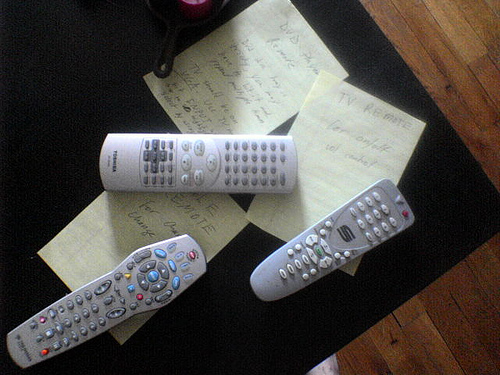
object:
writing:
[326, 88, 421, 178]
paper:
[244, 70, 428, 278]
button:
[145, 269, 160, 285]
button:
[98, 317, 106, 326]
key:
[388, 217, 399, 228]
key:
[321, 216, 331, 231]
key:
[279, 268, 289, 279]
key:
[170, 276, 181, 290]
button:
[401, 208, 409, 218]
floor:
[295, 1, 496, 373]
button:
[80, 308, 90, 319]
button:
[127, 284, 135, 294]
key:
[373, 191, 382, 202]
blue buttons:
[170, 276, 183, 290]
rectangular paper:
[141, 0, 352, 146]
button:
[136, 293, 143, 299]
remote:
[248, 178, 417, 303]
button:
[303, 231, 322, 246]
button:
[152, 247, 169, 259]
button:
[92, 280, 112, 295]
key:
[388, 216, 398, 228]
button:
[122, 272, 132, 281]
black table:
[0, 0, 500, 373]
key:
[380, 204, 391, 216]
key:
[349, 207, 358, 218]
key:
[364, 231, 374, 243]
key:
[365, 214, 375, 226]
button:
[207, 153, 218, 173]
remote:
[97, 132, 297, 194]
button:
[63, 318, 72, 328]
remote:
[5, 232, 207, 370]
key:
[364, 196, 373, 207]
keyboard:
[274, 190, 412, 283]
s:
[335, 223, 356, 242]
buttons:
[314, 246, 325, 258]